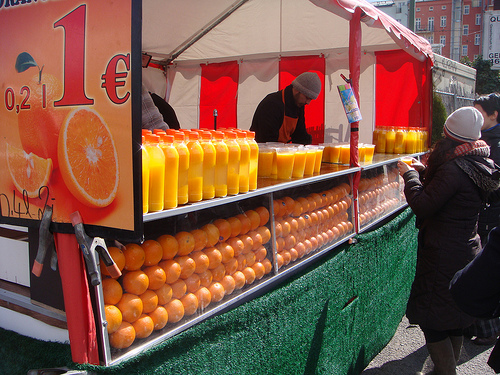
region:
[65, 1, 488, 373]
a shop kept open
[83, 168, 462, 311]
orange fruits in the rack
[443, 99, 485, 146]
a man wearing cap in his head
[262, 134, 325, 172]
juices kept in the glass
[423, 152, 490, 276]
a person wearing black color sweater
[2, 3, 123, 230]
advertisement in the side of the shop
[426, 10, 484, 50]
windows in the building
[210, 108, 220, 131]
handle of the door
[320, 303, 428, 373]
shadow of the person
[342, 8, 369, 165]
metal stand of the tent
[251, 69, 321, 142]
a man wearing an apron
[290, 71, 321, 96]
a man's stocking cap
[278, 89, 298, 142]
a man's orange apron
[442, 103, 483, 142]
a woman's stocking cap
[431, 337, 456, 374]
a woman's left boot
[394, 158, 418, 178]
a woman's left hand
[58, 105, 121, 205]
half of an orange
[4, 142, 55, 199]
an orange slice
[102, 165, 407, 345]
stacks of many oranges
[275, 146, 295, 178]
a glass of fresh squeezed orange juice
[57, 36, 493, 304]
orange juice for sale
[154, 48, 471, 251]
fresh orange juice for sale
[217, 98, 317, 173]
glasses of orange juice for sale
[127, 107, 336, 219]
bottles of orange juice for sale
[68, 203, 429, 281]
oranges that are on display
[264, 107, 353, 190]
glasses of orange juice on display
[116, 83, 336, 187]
bottle of orange juices display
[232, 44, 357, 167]
a man wearing an apron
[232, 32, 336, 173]
a man wearing a beanie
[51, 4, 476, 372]
a man standing under a tent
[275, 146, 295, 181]
a cup of orange juice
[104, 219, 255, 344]
a stack of oranges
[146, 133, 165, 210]
a bottle of orange juice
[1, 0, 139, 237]
an advertisement banner on the booth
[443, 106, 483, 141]
a white knit cap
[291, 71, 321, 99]
the man has a grey knit cap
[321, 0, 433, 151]
a red and white canvas booth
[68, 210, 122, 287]
metal clamps securing the banner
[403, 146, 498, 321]
a lady wearing a long winter coat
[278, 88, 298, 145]
the man is wearing a red apron